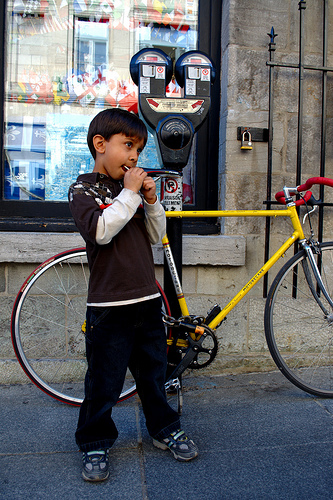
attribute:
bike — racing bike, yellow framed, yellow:
[8, 175, 331, 406]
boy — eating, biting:
[70, 109, 199, 482]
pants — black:
[73, 295, 181, 454]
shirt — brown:
[68, 170, 160, 305]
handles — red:
[270, 176, 332, 209]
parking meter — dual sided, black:
[129, 46, 215, 168]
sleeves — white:
[94, 191, 167, 248]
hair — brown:
[86, 110, 147, 157]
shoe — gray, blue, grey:
[151, 428, 200, 461]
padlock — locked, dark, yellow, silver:
[240, 130, 252, 152]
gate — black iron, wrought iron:
[239, 0, 330, 300]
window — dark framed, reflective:
[4, 0, 199, 204]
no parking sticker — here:
[157, 175, 182, 209]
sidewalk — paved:
[1, 365, 331, 498]